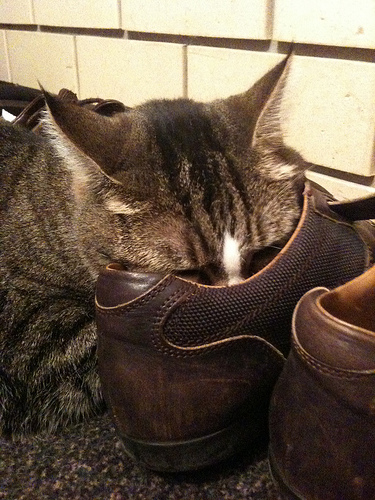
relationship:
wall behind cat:
[3, 0, 374, 210] [5, 39, 309, 448]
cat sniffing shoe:
[5, 39, 309, 448] [91, 183, 374, 475]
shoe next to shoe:
[91, 183, 374, 475] [263, 251, 373, 497]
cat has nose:
[5, 39, 309, 448] [215, 277, 251, 291]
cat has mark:
[5, 39, 309, 448] [219, 229, 245, 277]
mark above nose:
[219, 229, 245, 277] [215, 277, 251, 291]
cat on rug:
[5, 39, 309, 448] [4, 411, 281, 499]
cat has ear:
[5, 39, 309, 448] [36, 80, 121, 196]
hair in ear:
[41, 112, 105, 188] [36, 80, 121, 196]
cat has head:
[5, 39, 309, 448] [37, 39, 306, 304]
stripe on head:
[153, 108, 195, 222] [37, 39, 306, 304]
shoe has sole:
[91, 183, 374, 475] [117, 409, 270, 476]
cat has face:
[5, 39, 309, 448] [143, 214, 298, 291]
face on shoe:
[143, 214, 298, 291] [91, 183, 374, 475]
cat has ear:
[5, 39, 309, 448] [231, 38, 297, 165]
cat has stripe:
[5, 39, 309, 448] [208, 122, 259, 236]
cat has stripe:
[5, 39, 309, 448] [190, 214, 217, 262]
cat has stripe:
[5, 39, 309, 448] [153, 108, 195, 222]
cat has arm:
[5, 39, 309, 448] [3, 286, 109, 441]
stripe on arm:
[7, 286, 84, 352] [3, 286, 109, 441]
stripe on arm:
[28, 313, 92, 384] [3, 286, 109, 441]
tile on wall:
[74, 31, 188, 113] [3, 0, 374, 210]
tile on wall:
[187, 43, 374, 181] [3, 0, 374, 210]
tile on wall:
[5, 28, 83, 101] [3, 0, 374, 210]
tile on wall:
[120, 2, 274, 44] [3, 0, 374, 210]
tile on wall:
[274, 2, 373, 56] [3, 0, 374, 210]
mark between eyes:
[219, 229, 245, 277] [165, 237, 285, 280]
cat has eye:
[5, 39, 309, 448] [169, 264, 211, 280]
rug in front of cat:
[4, 411, 281, 499] [5, 39, 309, 448]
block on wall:
[1, 2, 37, 29] [3, 0, 374, 210]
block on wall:
[32, 0, 123, 31] [3, 0, 374, 210]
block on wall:
[294, 167, 374, 210] [3, 0, 374, 210]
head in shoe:
[37, 39, 306, 304] [91, 183, 374, 475]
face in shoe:
[143, 214, 298, 291] [91, 183, 374, 475]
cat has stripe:
[5, 39, 309, 448] [7, 286, 84, 352]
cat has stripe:
[5, 39, 309, 448] [28, 313, 92, 384]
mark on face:
[219, 229, 245, 277] [143, 214, 298, 291]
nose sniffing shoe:
[215, 277, 251, 291] [91, 183, 374, 475]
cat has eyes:
[5, 39, 309, 448] [165, 237, 285, 280]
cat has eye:
[5, 39, 309, 448] [252, 239, 283, 260]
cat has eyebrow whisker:
[5, 39, 309, 448] [254, 240, 288, 253]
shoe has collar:
[91, 183, 374, 475] [106, 180, 321, 313]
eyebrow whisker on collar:
[254, 240, 288, 253] [106, 180, 321, 313]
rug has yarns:
[4, 411, 281, 499] [27, 436, 121, 481]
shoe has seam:
[91, 183, 374, 475] [146, 284, 231, 360]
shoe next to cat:
[91, 183, 374, 475] [5, 39, 309, 448]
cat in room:
[5, 39, 309, 448] [1, 1, 373, 497]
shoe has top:
[263, 251, 373, 497] [288, 262, 374, 382]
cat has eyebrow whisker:
[5, 39, 309, 448] [272, 153, 327, 201]